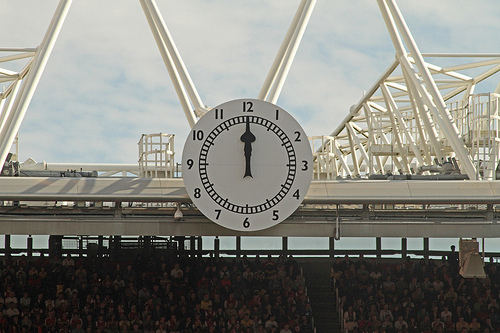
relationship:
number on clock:
[285, 187, 315, 203] [173, 90, 319, 245]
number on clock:
[212, 206, 224, 221] [173, 90, 319, 245]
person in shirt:
[170, 259, 184, 279] [170, 270, 182, 277]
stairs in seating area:
[298, 257, 350, 329] [1, 251, 496, 329]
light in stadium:
[455, 237, 490, 280] [0, 230, 500, 330]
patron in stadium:
[265, 312, 277, 328] [2, 2, 484, 330]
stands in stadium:
[1, 253, 499, 330] [0, 158, 497, 331]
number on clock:
[238, 215, 253, 230] [184, 98, 311, 235]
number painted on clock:
[190, 129, 205, 141] [184, 98, 311, 235]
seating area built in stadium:
[1, 251, 496, 329] [2, 2, 484, 330]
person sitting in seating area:
[170, 263, 182, 278] [1, 251, 496, 329]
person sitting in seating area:
[200, 293, 212, 309] [1, 251, 496, 329]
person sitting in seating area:
[380, 304, 394, 321] [1, 251, 496, 329]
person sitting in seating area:
[381, 274, 397, 292] [1, 251, 496, 329]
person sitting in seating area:
[431, 275, 444, 291] [1, 251, 496, 329]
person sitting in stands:
[200, 293, 212, 309] [1, 246, 484, 330]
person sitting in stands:
[170, 261, 185, 276] [1, 246, 484, 330]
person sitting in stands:
[53, 292, 67, 305] [1, 246, 484, 330]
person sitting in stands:
[381, 275, 395, 291] [1, 246, 484, 330]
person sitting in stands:
[440, 306, 454, 321] [1, 246, 484, 330]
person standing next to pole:
[442, 242, 463, 267] [459, 235, 485, 285]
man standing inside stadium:
[448, 244, 460, 265] [2, 2, 484, 330]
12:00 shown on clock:
[240, 100, 255, 179] [178, 92, 313, 234]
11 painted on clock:
[209, 105, 230, 122] [184, 98, 311, 235]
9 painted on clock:
[184, 158, 196, 174] [180, 87, 323, 240]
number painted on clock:
[272, 204, 294, 232] [184, 98, 311, 235]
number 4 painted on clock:
[291, 188, 301, 201] [135, 59, 372, 271]